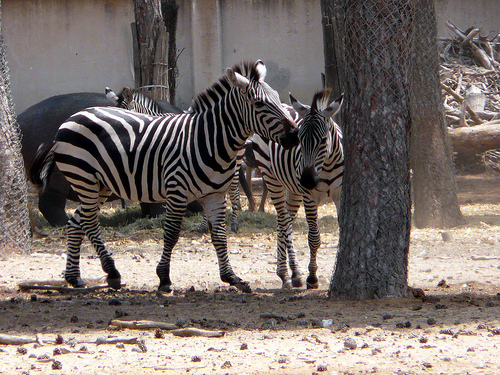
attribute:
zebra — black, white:
[37, 59, 300, 298]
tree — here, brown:
[325, 2, 416, 299]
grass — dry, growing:
[25, 188, 315, 245]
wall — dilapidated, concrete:
[1, 0, 494, 125]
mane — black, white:
[183, 58, 253, 118]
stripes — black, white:
[56, 107, 245, 192]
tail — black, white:
[27, 138, 57, 194]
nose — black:
[281, 124, 301, 144]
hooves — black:
[57, 259, 331, 295]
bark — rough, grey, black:
[328, 1, 417, 300]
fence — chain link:
[0, 44, 35, 258]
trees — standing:
[323, 2, 464, 302]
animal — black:
[14, 91, 179, 217]